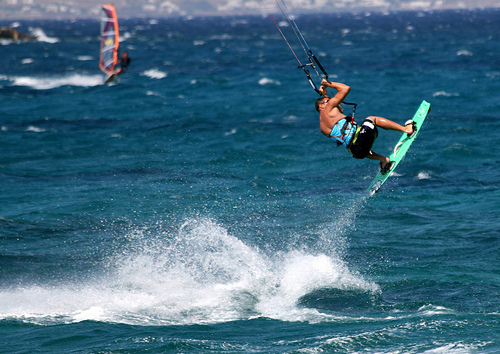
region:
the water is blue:
[114, 132, 273, 183]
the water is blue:
[85, 130, 258, 215]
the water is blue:
[85, 131, 318, 213]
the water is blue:
[45, 130, 238, 213]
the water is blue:
[100, 121, 260, 187]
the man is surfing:
[277, 61, 454, 234]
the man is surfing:
[255, 39, 464, 232]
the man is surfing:
[262, 29, 452, 239]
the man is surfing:
[250, 36, 467, 202]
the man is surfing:
[281, 54, 446, 228]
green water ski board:
[360, 87, 433, 219]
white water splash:
[90, 209, 377, 279]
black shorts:
[336, 111, 381, 163]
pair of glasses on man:
[311, 90, 338, 106]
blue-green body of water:
[0, 1, 494, 352]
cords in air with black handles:
[254, 1, 343, 95]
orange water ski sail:
[85, 3, 128, 83]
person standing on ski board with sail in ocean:
[80, 1, 141, 106]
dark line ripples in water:
[50, 133, 197, 184]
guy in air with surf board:
[261, 15, 442, 204]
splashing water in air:
[150, 204, 295, 314]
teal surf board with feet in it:
[359, 94, 436, 208]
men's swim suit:
[327, 120, 379, 160]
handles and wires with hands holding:
[261, 7, 336, 96]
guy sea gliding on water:
[83, 9, 135, 86]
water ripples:
[145, 126, 189, 160]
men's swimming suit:
[104, 51, 132, 75]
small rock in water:
[3, 24, 43, 55]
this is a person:
[278, 65, 394, 174]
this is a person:
[106, 43, 142, 85]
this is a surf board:
[352, 86, 437, 197]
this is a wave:
[278, 244, 341, 344]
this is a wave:
[179, 255, 256, 339]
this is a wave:
[181, 214, 236, 297]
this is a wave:
[104, 255, 181, 335]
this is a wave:
[199, 240, 258, 310]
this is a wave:
[91, 265, 146, 326]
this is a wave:
[295, 236, 347, 320]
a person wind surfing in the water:
[94, 7, 129, 77]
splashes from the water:
[183, 181, 271, 256]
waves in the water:
[142, 255, 412, 337]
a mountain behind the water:
[7, 2, 455, 35]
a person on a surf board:
[286, 38, 436, 234]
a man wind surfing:
[270, 34, 439, 215]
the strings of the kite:
[260, 2, 331, 97]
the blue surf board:
[357, 90, 427, 203]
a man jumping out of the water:
[302, 70, 408, 190]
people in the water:
[74, 21, 466, 221]